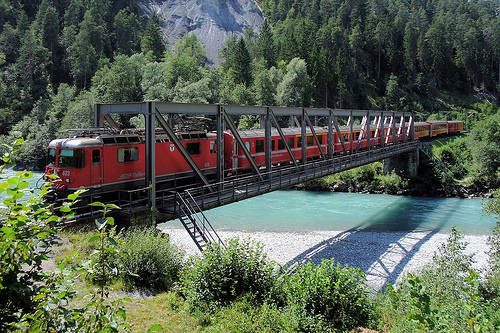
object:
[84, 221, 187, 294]
plant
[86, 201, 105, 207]
green leaf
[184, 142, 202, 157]
window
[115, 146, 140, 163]
window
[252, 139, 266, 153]
window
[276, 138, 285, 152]
window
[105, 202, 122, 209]
leaf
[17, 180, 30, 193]
leaf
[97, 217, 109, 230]
leaf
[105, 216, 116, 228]
leaf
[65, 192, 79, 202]
leaf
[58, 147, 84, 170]
window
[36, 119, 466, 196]
train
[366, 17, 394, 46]
leaf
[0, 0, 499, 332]
outdoors scene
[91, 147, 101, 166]
window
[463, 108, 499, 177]
plant